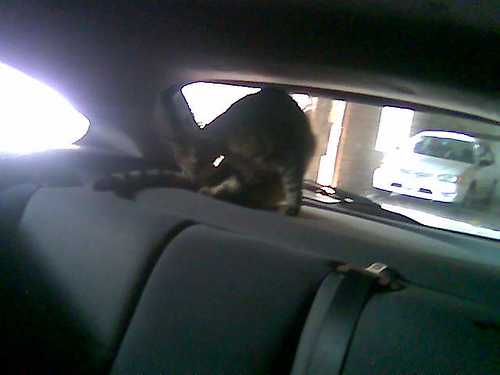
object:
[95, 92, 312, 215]
cat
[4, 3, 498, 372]
car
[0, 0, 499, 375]
photo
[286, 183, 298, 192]
stripes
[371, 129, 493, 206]
car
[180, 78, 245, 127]
light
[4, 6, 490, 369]
inside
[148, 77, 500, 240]
back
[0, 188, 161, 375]
seat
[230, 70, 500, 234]
background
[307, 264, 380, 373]
belt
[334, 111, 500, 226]
garage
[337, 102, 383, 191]
brick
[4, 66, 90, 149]
sun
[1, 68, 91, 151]
window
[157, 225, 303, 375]
seats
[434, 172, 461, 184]
headlights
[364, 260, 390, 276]
buckle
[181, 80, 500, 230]
window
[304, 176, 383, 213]
wiper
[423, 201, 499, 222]
ground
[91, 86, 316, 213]
itself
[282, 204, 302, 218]
paws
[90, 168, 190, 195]
tail